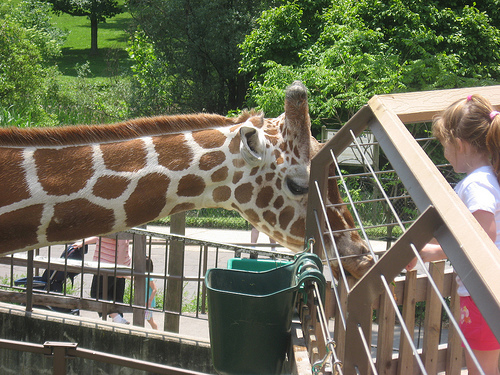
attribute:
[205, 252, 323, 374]
bins — green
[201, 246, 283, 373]
buckets — green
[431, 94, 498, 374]
girl — little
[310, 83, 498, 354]
railing — wooden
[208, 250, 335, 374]
bucket — green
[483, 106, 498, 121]
hair tie — pink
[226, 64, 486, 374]
railing — wood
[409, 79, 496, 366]
girl — standing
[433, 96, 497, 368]
child — walking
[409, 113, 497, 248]
girl — little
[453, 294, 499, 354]
shorts — red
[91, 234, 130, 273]
shirt — pink, striped